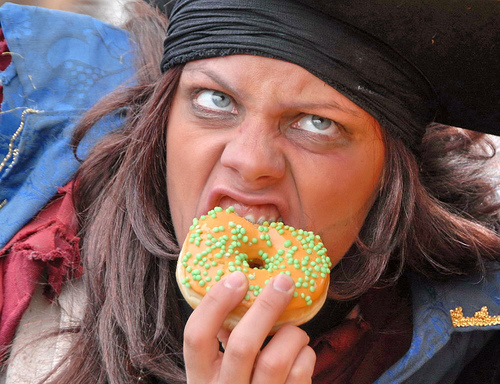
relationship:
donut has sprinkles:
[181, 162, 340, 355] [201, 222, 259, 255]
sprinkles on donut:
[201, 222, 259, 255] [181, 162, 340, 355]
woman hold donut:
[135, 23, 403, 353] [181, 162, 340, 355]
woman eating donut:
[135, 23, 403, 353] [181, 162, 340, 355]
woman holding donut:
[135, 23, 403, 353] [181, 162, 340, 355]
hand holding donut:
[147, 262, 310, 356] [181, 162, 340, 355]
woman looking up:
[135, 23, 403, 353] [193, 22, 356, 139]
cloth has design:
[4, 10, 89, 194] [448, 295, 499, 328]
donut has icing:
[181, 162, 340, 355] [188, 223, 331, 308]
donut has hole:
[181, 162, 340, 355] [236, 246, 273, 277]